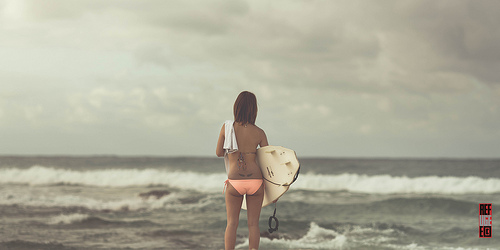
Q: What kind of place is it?
A: It is an ocean.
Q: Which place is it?
A: It is an ocean.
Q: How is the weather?
A: It is overcast.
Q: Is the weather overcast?
A: Yes, it is overcast.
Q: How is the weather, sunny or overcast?
A: It is overcast.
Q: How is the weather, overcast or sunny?
A: It is overcast.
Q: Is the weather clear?
A: No, it is overcast.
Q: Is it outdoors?
A: Yes, it is outdoors.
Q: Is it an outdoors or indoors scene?
A: It is outdoors.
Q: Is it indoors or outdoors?
A: It is outdoors.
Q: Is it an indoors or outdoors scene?
A: It is outdoors.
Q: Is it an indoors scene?
A: No, it is outdoors.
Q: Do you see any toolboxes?
A: No, there are no toolboxes.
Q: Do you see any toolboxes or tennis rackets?
A: No, there are no toolboxes or tennis rackets.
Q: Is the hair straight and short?
A: Yes, the hair is straight and short.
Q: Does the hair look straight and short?
A: Yes, the hair is straight and short.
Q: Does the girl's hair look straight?
A: Yes, the hair is straight.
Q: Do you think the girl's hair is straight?
A: Yes, the hair is straight.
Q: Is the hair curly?
A: No, the hair is straight.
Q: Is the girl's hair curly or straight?
A: The hair is straight.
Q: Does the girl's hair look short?
A: Yes, the hair is short.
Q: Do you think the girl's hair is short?
A: Yes, the hair is short.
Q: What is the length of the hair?
A: The hair is short.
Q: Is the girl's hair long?
A: No, the hair is short.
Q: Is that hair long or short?
A: The hair is short.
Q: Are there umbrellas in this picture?
A: No, there are no umbrellas.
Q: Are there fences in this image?
A: No, there are no fences.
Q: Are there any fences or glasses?
A: No, there are no fences or glasses.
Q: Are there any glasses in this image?
A: No, there are no glasses.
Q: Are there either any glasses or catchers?
A: No, there are no glasses or catchers.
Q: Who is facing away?
A: The girl is facing away.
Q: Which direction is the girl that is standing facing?
A: The girl is facing away.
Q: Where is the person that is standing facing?
A: The girl is facing away.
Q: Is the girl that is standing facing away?
A: Yes, the girl is facing away.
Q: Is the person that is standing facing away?
A: Yes, the girl is facing away.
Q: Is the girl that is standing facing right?
A: No, the girl is facing away.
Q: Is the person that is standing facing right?
A: No, the girl is facing away.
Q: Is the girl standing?
A: Yes, the girl is standing.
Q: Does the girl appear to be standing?
A: Yes, the girl is standing.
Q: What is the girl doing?
A: The girl is standing.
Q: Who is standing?
A: The girl is standing.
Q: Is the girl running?
A: No, the girl is standing.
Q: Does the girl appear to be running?
A: No, the girl is standing.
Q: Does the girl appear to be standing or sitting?
A: The girl is standing.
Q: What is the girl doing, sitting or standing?
A: The girl is standing.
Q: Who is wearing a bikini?
A: The girl is wearing a bikini.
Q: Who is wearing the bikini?
A: The girl is wearing a bikini.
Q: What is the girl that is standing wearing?
A: The girl is wearing a bikini.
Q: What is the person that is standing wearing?
A: The girl is wearing a bikini.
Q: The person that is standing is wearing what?
A: The girl is wearing a bikini.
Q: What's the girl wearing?
A: The girl is wearing a bikini.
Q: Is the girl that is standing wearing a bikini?
A: Yes, the girl is wearing a bikini.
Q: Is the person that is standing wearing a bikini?
A: Yes, the girl is wearing a bikini.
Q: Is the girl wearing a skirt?
A: No, the girl is wearing a bikini.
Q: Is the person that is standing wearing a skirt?
A: No, the girl is wearing a bikini.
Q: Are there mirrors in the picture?
A: No, there are no mirrors.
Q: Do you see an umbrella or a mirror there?
A: No, there are no mirrors or umbrellas.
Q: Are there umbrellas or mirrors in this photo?
A: No, there are no mirrors or umbrellas.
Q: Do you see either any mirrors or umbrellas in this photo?
A: No, there are no mirrors or umbrellas.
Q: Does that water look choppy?
A: Yes, the water is choppy.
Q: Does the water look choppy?
A: Yes, the water is choppy.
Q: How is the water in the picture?
A: The water is choppy.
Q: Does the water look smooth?
A: No, the water is choppy.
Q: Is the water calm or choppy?
A: The water is choppy.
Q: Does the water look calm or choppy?
A: The water is choppy.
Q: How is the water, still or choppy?
A: The water is choppy.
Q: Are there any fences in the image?
A: No, there are no fences.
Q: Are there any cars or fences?
A: No, there are no fences or cars.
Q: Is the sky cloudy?
A: Yes, the sky is cloudy.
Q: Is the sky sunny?
A: No, the sky is cloudy.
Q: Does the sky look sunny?
A: No, the sky is cloudy.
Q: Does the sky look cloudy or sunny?
A: The sky is cloudy.